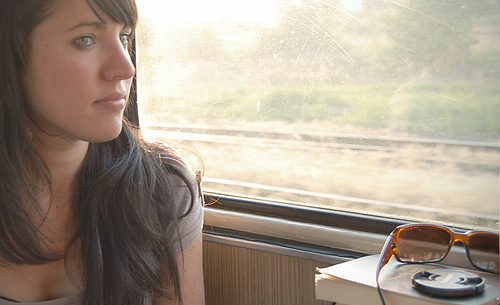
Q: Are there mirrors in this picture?
A: No, there are no mirrors.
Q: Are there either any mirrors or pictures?
A: No, there are no mirrors or pictures.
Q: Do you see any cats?
A: No, there are no cats.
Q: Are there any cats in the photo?
A: No, there are no cats.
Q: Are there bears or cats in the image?
A: No, there are no cats or bears.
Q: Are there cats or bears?
A: No, there are no cats or bears.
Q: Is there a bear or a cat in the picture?
A: No, there are no cats or bears.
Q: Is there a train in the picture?
A: Yes, there is a train.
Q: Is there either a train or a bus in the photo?
A: Yes, there is a train.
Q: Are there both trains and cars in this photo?
A: No, there is a train but no cars.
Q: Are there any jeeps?
A: No, there are no jeeps.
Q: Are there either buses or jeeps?
A: No, there are no jeeps or buses.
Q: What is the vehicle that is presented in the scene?
A: The vehicle is a train.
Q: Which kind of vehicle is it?
A: The vehicle is a train.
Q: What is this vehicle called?
A: This is a train.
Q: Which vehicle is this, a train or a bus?
A: This is a train.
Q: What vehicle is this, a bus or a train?
A: This is a train.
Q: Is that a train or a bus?
A: That is a train.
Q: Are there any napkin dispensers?
A: No, there are no napkin dispensers.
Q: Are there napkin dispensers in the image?
A: No, there are no napkin dispensers.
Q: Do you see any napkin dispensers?
A: No, there are no napkin dispensers.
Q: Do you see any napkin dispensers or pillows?
A: No, there are no napkin dispensers or pillows.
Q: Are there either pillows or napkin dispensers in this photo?
A: No, there are no napkin dispensers or pillows.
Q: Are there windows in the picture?
A: Yes, there is a window.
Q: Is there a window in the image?
A: Yes, there is a window.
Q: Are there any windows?
A: Yes, there is a window.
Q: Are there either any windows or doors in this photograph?
A: Yes, there is a window.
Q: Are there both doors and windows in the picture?
A: No, there is a window but no doors.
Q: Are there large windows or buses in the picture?
A: Yes, there is a large window.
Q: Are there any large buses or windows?
A: Yes, there is a large window.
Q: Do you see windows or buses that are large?
A: Yes, the window is large.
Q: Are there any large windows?
A: Yes, there is a large window.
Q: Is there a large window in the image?
A: Yes, there is a large window.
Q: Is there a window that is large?
A: Yes, there is a window that is large.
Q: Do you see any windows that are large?
A: Yes, there is a window that is large.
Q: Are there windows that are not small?
A: Yes, there is a large window.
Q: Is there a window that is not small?
A: Yes, there is a large window.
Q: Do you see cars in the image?
A: No, there are no cars.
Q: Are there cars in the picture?
A: No, there are no cars.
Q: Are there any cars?
A: No, there are no cars.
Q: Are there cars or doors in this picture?
A: No, there are no cars or doors.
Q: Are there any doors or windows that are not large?
A: No, there is a window but it is large.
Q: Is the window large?
A: Yes, the window is large.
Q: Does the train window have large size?
A: Yes, the window is large.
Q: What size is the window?
A: The window is large.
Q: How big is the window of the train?
A: The window is large.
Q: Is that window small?
A: No, the window is large.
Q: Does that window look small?
A: No, the window is large.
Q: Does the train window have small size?
A: No, the window is large.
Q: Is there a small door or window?
A: No, there is a window but it is large.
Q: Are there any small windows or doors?
A: No, there is a window but it is large.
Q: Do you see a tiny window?
A: No, there is a window but it is large.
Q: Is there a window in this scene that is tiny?
A: No, there is a window but it is large.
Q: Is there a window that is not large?
A: No, there is a window but it is large.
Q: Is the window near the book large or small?
A: The window is large.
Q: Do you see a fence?
A: No, there are no fences.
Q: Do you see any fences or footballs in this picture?
A: No, there are no fences or footballs.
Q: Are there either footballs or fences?
A: No, there are no fences or footballs.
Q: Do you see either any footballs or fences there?
A: No, there are no fences or footballs.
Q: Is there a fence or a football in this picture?
A: No, there are no fences or footballs.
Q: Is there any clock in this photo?
A: No, there are no clocks.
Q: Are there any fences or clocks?
A: No, there are no clocks or fences.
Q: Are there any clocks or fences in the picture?
A: No, there are no clocks or fences.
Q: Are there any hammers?
A: No, there are no hammers.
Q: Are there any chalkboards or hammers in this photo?
A: No, there are no hammers or chalkboards.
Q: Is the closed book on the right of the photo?
A: Yes, the book is on the right of the image.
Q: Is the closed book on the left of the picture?
A: No, the book is on the right of the image.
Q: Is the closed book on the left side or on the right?
A: The book is on the right of the image.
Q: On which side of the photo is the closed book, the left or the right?
A: The book is on the right of the image.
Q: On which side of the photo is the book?
A: The book is on the right of the image.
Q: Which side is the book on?
A: The book is on the right of the image.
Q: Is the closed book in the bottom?
A: Yes, the book is in the bottom of the image.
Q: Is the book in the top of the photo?
A: No, the book is in the bottom of the image.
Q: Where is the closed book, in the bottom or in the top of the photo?
A: The book is in the bottom of the image.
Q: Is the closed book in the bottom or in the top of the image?
A: The book is in the bottom of the image.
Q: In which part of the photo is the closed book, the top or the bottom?
A: The book is in the bottom of the image.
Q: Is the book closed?
A: Yes, the book is closed.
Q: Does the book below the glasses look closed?
A: Yes, the book is closed.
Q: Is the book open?
A: No, the book is closed.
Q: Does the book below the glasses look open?
A: No, the book is closed.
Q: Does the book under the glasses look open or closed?
A: The book is closed.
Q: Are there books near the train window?
A: Yes, there is a book near the window.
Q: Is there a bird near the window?
A: No, there is a book near the window.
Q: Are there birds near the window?
A: No, there is a book near the window.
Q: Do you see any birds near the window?
A: No, there is a book near the window.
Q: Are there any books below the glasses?
A: Yes, there is a book below the glasses.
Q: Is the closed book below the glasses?
A: Yes, the book is below the glasses.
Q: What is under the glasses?
A: The book is under the glasses.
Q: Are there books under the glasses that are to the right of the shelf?
A: Yes, there is a book under the glasses.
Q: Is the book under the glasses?
A: Yes, the book is under the glasses.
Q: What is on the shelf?
A: The book is on the shelf.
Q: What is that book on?
A: The book is on the shelf.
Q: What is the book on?
A: The book is on the shelf.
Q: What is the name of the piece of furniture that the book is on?
A: The piece of furniture is a shelf.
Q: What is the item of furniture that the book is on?
A: The piece of furniture is a shelf.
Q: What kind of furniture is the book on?
A: The book is on the shelf.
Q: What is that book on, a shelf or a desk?
A: The book is on a shelf.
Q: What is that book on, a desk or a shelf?
A: The book is on a shelf.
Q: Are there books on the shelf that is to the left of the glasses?
A: Yes, there is a book on the shelf.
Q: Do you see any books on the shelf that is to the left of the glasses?
A: Yes, there is a book on the shelf.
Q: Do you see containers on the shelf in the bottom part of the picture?
A: No, there is a book on the shelf.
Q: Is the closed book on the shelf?
A: Yes, the book is on the shelf.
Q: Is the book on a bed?
A: No, the book is on the shelf.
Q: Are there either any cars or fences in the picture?
A: No, there are no cars or fences.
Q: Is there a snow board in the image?
A: No, there are no snowboards.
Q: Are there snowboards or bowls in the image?
A: No, there are no snowboards or bowls.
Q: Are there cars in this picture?
A: No, there are no cars.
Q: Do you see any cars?
A: No, there are no cars.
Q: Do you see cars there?
A: No, there are no cars.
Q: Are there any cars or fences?
A: No, there are no cars or fences.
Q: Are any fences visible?
A: No, there are no fences.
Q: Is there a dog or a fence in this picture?
A: No, there are no fences or dogs.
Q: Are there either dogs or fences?
A: No, there are no fences or dogs.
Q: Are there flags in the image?
A: No, there are no flags.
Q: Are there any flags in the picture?
A: No, there are no flags.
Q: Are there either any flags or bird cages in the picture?
A: No, there are no flags or bird cages.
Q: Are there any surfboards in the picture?
A: No, there are no surfboards.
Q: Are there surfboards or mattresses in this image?
A: No, there are no surfboards or mattresses.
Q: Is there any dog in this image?
A: No, there are no dogs.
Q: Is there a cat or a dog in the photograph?
A: No, there are no dogs or cats.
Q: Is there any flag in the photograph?
A: No, there are no flags.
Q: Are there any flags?
A: No, there are no flags.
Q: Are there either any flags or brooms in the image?
A: No, there are no flags or brooms.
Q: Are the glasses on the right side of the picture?
A: Yes, the glasses are on the right of the image.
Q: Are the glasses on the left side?
A: No, the glasses are on the right of the image.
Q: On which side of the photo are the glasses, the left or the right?
A: The glasses are on the right of the image.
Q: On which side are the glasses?
A: The glasses are on the right of the image.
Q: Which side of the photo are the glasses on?
A: The glasses are on the right of the image.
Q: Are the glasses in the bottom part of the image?
A: Yes, the glasses are in the bottom of the image.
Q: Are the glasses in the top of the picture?
A: No, the glasses are in the bottom of the image.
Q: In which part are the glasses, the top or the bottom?
A: The glasses are in the bottom of the image.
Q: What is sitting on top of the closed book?
A: The glasses are sitting on top of the book.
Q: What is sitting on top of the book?
A: The glasses are sitting on top of the book.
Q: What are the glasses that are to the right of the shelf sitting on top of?
A: The glasses are sitting on top of the book.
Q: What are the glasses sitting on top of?
A: The glasses are sitting on top of the book.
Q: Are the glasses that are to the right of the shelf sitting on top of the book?
A: Yes, the glasses are sitting on top of the book.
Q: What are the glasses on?
A: The glasses are on the book.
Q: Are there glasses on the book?
A: Yes, there are glasses on the book.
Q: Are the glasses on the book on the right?
A: Yes, the glasses are on the book.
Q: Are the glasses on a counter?
A: No, the glasses are on the book.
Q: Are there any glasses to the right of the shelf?
A: Yes, there are glasses to the right of the shelf.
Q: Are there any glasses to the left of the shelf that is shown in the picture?
A: No, the glasses are to the right of the shelf.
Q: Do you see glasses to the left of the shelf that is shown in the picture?
A: No, the glasses are to the right of the shelf.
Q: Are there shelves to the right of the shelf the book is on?
A: No, there are glasses to the right of the shelf.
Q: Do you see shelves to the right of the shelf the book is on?
A: No, there are glasses to the right of the shelf.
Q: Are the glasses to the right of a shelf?
A: Yes, the glasses are to the right of a shelf.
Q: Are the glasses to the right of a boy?
A: No, the glasses are to the right of a shelf.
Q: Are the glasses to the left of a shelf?
A: No, the glasses are to the right of a shelf.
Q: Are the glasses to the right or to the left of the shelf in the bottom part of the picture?
A: The glasses are to the right of the shelf.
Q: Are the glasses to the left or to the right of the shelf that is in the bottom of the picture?
A: The glasses are to the right of the shelf.